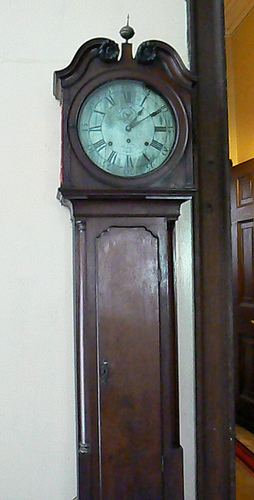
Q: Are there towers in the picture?
A: No, there are no towers.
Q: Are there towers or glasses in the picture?
A: No, there are no towers or glasses.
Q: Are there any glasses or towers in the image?
A: No, there are no towers or glasses.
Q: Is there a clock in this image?
A: Yes, there is a clock.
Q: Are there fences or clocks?
A: Yes, there is a clock.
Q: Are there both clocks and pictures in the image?
A: No, there is a clock but no pictures.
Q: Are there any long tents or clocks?
A: Yes, there is a long clock.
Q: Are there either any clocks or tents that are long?
A: Yes, the clock is long.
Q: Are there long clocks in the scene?
A: Yes, there is a long clock.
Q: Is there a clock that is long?
A: Yes, there is a clock that is long.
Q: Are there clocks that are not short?
A: Yes, there is a long clock.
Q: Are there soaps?
A: No, there are no soaps.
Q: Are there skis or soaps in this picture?
A: No, there are no soaps or skis.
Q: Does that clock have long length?
A: Yes, the clock is long.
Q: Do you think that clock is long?
A: Yes, the clock is long.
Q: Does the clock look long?
A: Yes, the clock is long.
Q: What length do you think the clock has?
A: The clock has long length.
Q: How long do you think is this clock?
A: The clock is long.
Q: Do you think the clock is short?
A: No, the clock is long.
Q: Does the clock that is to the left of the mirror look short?
A: No, the clock is long.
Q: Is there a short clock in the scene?
A: No, there is a clock but it is long.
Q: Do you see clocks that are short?
A: No, there is a clock but it is long.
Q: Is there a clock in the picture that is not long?
A: No, there is a clock but it is long.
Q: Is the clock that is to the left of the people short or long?
A: The clock is long.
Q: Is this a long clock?
A: Yes, this is a long clock.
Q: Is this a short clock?
A: No, this is a long clock.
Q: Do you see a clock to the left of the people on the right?
A: Yes, there is a clock to the left of the people.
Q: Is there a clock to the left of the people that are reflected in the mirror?
A: Yes, there is a clock to the left of the people.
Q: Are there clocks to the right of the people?
A: No, the clock is to the left of the people.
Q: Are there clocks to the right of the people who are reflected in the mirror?
A: No, the clock is to the left of the people.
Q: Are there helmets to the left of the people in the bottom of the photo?
A: No, there is a clock to the left of the people.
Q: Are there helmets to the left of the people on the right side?
A: No, there is a clock to the left of the people.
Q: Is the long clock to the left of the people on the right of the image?
A: Yes, the clock is to the left of the people.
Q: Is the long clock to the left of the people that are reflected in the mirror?
A: Yes, the clock is to the left of the people.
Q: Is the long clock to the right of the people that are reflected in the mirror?
A: No, the clock is to the left of the people.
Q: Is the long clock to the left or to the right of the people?
A: The clock is to the left of the people.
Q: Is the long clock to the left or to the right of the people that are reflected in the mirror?
A: The clock is to the left of the people.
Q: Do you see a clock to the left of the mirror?
A: Yes, there is a clock to the left of the mirror.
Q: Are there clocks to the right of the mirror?
A: No, the clock is to the left of the mirror.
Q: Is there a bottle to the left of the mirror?
A: No, there is a clock to the left of the mirror.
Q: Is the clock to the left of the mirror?
A: Yes, the clock is to the left of the mirror.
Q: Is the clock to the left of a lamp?
A: No, the clock is to the left of the mirror.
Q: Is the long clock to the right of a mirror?
A: No, the clock is to the left of a mirror.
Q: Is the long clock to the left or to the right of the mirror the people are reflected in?
A: The clock is to the left of the mirror.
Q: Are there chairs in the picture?
A: No, there are no chairs.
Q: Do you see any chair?
A: No, there are no chairs.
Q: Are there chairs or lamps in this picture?
A: No, there are no chairs or lamps.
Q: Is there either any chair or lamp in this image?
A: No, there are no chairs or lamps.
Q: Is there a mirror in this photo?
A: Yes, there is a mirror.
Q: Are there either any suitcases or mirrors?
A: Yes, there is a mirror.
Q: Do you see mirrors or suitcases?
A: Yes, there is a mirror.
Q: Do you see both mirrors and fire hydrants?
A: No, there is a mirror but no fire hydrants.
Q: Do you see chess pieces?
A: No, there are no chess pieces.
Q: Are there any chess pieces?
A: No, there are no chess pieces.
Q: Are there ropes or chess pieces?
A: No, there are no chess pieces or ropes.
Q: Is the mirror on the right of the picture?
A: Yes, the mirror is on the right of the image.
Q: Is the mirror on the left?
A: No, the mirror is on the right of the image.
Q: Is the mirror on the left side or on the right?
A: The mirror is on the right of the image.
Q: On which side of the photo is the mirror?
A: The mirror is on the right of the image.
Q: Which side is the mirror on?
A: The mirror is on the right of the image.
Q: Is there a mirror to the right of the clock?
A: Yes, there is a mirror to the right of the clock.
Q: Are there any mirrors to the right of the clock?
A: Yes, there is a mirror to the right of the clock.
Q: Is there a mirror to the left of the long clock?
A: No, the mirror is to the right of the clock.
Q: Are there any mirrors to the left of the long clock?
A: No, the mirror is to the right of the clock.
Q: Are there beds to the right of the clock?
A: No, there is a mirror to the right of the clock.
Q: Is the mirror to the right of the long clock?
A: Yes, the mirror is to the right of the clock.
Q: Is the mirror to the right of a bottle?
A: No, the mirror is to the right of the clock.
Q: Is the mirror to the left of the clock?
A: No, the mirror is to the right of the clock.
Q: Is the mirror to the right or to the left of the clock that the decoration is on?
A: The mirror is to the right of the clock.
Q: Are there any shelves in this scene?
A: No, there are no shelves.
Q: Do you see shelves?
A: No, there are no shelves.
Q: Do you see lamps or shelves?
A: No, there are no shelves or lamps.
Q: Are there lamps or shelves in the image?
A: No, there are no shelves or lamps.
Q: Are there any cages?
A: No, there are no cages.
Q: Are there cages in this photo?
A: No, there are no cages.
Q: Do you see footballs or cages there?
A: No, there are no cages or footballs.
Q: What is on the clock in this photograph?
A: The decoration is on the clock.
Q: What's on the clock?
A: The decoration is on the clock.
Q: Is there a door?
A: Yes, there is a door.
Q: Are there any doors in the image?
A: Yes, there is a door.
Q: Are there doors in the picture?
A: Yes, there is a door.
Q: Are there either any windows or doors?
A: Yes, there is a door.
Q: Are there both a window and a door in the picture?
A: No, there is a door but no windows.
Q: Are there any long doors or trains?
A: Yes, there is a long door.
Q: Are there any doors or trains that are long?
A: Yes, the door is long.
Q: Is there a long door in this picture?
A: Yes, there is a long door.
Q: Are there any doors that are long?
A: Yes, there is a door that is long.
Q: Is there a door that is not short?
A: Yes, there is a long door.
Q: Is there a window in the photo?
A: No, there are no windows.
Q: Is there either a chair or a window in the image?
A: No, there are no windows or chairs.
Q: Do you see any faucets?
A: No, there are no faucets.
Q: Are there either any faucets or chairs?
A: No, there are no faucets or chairs.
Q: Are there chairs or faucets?
A: No, there are no faucets or chairs.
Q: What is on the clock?
A: The decoration is on the clock.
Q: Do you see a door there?
A: Yes, there is a door.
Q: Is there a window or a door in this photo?
A: Yes, there is a door.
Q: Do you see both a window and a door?
A: No, there is a door but no windows.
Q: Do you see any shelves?
A: No, there are no shelves.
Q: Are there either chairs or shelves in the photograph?
A: No, there are no shelves or chairs.